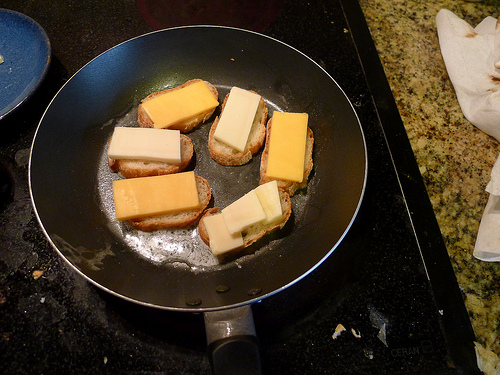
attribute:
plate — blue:
[2, 9, 52, 122]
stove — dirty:
[3, 1, 471, 373]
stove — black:
[260, 185, 457, 374]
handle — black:
[176, 310, 256, 365]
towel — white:
[437, 10, 499, 264]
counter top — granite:
[382, 12, 498, 219]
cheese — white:
[103, 122, 185, 164]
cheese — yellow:
[109, 173, 206, 219]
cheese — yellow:
[262, 109, 309, 182]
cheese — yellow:
[140, 81, 219, 126]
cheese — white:
[203, 181, 281, 257]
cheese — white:
[210, 84, 261, 152]